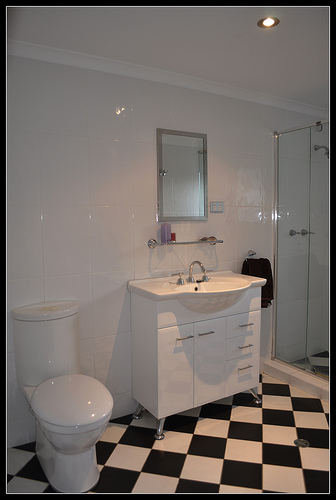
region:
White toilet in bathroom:
[10, 300, 120, 491]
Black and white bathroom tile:
[119, 407, 319, 483]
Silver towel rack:
[133, 229, 233, 257]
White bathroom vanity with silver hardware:
[128, 291, 309, 424]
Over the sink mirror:
[149, 114, 223, 234]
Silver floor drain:
[284, 426, 320, 459]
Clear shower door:
[252, 116, 324, 378]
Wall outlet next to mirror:
[208, 194, 229, 219]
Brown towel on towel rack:
[243, 245, 297, 330]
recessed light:
[222, 10, 306, 53]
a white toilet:
[9, 299, 116, 493]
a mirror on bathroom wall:
[155, 127, 209, 223]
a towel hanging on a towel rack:
[241, 257, 274, 308]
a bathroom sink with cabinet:
[126, 269, 268, 438]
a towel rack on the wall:
[148, 235, 225, 247]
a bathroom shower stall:
[273, 121, 329, 384]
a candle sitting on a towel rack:
[161, 223, 172, 242]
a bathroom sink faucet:
[170, 258, 216, 285]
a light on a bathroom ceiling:
[255, 14, 280, 30]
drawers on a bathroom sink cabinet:
[224, 306, 260, 398]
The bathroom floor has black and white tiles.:
[130, 429, 321, 476]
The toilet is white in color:
[8, 286, 130, 499]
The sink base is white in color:
[129, 280, 286, 426]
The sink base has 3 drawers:
[229, 311, 270, 437]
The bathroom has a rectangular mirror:
[153, 119, 223, 231]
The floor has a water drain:
[286, 416, 319, 475]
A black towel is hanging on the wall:
[238, 231, 285, 313]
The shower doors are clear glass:
[271, 112, 331, 314]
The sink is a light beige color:
[127, 261, 290, 302]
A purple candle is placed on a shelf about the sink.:
[153, 207, 173, 248]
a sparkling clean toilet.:
[12, 298, 115, 490]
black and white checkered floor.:
[13, 372, 328, 490]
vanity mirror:
[154, 126, 211, 225]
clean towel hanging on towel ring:
[241, 248, 277, 309]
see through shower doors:
[273, 128, 330, 390]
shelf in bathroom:
[147, 220, 226, 248]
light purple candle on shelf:
[159, 221, 171, 246]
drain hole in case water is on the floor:
[291, 434, 312, 452]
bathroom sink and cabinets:
[125, 269, 262, 438]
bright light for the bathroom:
[255, 10, 282, 36]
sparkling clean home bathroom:
[7, 5, 329, 493]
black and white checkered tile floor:
[5, 371, 327, 493]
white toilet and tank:
[10, 298, 114, 491]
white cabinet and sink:
[127, 268, 265, 438]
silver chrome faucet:
[171, 260, 213, 284]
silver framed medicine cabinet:
[154, 126, 209, 222]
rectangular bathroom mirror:
[160, 134, 203, 217]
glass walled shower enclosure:
[260, 118, 329, 403]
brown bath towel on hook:
[240, 250, 274, 308]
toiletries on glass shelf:
[146, 222, 223, 246]